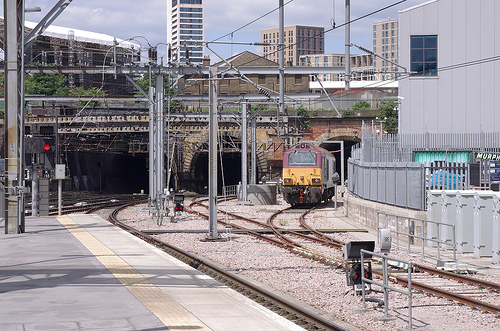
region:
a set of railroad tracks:
[80, 184, 369, 326]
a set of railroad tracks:
[183, 185, 275, 245]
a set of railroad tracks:
[268, 193, 497, 313]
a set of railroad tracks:
[34, 185, 144, 214]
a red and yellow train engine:
[277, 134, 336, 210]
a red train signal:
[37, 128, 54, 157]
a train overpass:
[18, 106, 385, 182]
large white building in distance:
[163, 0, 202, 70]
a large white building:
[21, 20, 138, 58]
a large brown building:
[258, 22, 326, 65]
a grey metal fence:
[340, 146, 426, 211]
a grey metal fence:
[349, 242, 421, 327]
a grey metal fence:
[365, 202, 465, 268]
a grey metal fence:
[357, 120, 410, 162]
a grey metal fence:
[398, 126, 493, 151]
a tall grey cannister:
[426, 185, 441, 245]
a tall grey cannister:
[439, 184, 456, 245]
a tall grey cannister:
[457, 186, 472, 251]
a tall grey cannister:
[474, 186, 490, 260]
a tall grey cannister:
[490, 190, 498, 267]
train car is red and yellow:
[276, 143, 334, 194]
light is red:
[33, 123, 72, 169]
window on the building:
[401, 34, 469, 90]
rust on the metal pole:
[0, 106, 27, 177]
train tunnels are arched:
[160, 137, 371, 190]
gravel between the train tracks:
[226, 225, 346, 321]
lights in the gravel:
[326, 249, 388, 303]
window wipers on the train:
[273, 140, 332, 161]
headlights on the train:
[277, 176, 324, 188]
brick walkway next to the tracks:
[90, 251, 170, 301]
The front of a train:
[248, 112, 356, 229]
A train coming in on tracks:
[263, 127, 491, 316]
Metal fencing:
[339, 134, 432, 214]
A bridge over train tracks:
[33, 70, 382, 211]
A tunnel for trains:
[168, 109, 277, 239]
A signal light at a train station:
[318, 226, 403, 311]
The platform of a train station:
[3, 112, 227, 329]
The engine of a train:
[260, 127, 352, 217]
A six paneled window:
[403, 25, 445, 90]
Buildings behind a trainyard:
[24, 2, 398, 130]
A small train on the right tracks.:
[278, 140, 333, 205]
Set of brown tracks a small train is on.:
[266, 203, 496, 315]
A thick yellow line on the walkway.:
[54, 213, 209, 330]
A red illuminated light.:
[42, 142, 49, 152]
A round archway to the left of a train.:
[180, 122, 270, 198]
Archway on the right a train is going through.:
[312, 122, 366, 184]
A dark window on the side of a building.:
[406, 33, 439, 78]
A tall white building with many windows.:
[170, 0, 207, 67]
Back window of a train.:
[285, 146, 317, 166]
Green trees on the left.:
[23, 68, 106, 98]